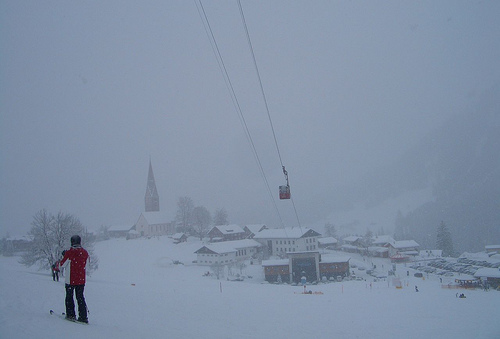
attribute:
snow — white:
[18, 225, 495, 339]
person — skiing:
[52, 230, 97, 329]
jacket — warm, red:
[60, 249, 93, 288]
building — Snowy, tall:
[260, 243, 354, 281]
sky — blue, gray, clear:
[3, 2, 500, 246]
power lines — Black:
[192, 1, 318, 239]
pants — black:
[66, 282, 88, 320]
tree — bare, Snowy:
[29, 200, 97, 270]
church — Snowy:
[134, 206, 174, 237]